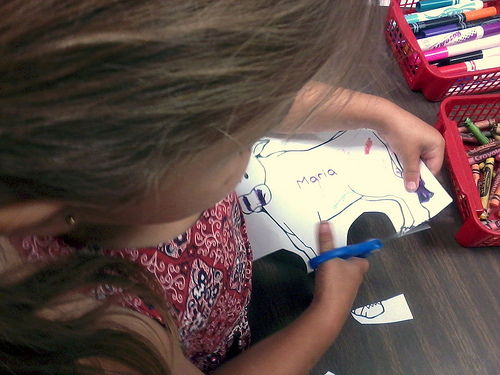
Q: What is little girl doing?
A: Cutting paper.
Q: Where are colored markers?
A: In bin.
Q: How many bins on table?
A: 2.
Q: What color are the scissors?
A: Blue.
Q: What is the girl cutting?
A: Paper.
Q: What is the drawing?
A: A cow.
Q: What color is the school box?
A: Red.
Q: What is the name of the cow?
A: Maria.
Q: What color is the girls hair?
A: Blonde.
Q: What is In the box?
A: Crayons.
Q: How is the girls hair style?
A: Ponytail.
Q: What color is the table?
A: Brown.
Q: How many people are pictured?
A: One.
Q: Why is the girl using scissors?
A: Cutting a cow.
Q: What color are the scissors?
A: Blue.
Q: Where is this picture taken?
A: A desk.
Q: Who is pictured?
A: A student.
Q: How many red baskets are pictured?
A: Two.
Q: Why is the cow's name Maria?
A: Little girls name.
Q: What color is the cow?
A: Black and white.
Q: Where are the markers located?
A: Red left basket.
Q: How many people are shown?
A: 1.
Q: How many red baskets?
A: 2.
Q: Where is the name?
A: On cow.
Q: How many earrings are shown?
A: 1.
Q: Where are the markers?
A: In red basket.